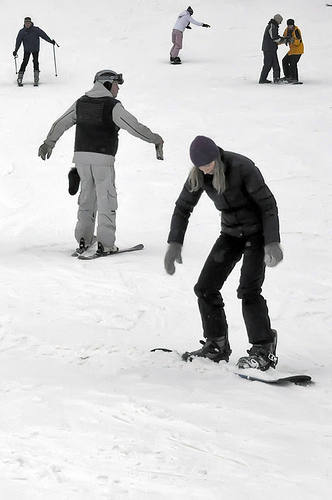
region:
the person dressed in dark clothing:
[154, 133, 310, 382]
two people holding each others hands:
[259, 13, 302, 84]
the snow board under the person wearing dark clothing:
[148, 345, 313, 382]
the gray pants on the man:
[69, 159, 119, 254]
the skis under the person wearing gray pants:
[71, 230, 144, 259]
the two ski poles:
[13, 40, 58, 76]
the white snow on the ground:
[1, 0, 329, 496]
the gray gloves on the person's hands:
[164, 242, 283, 273]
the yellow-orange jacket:
[282, 25, 302, 51]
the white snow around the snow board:
[139, 338, 317, 387]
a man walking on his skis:
[45, 59, 175, 262]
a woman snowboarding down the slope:
[149, 129, 331, 417]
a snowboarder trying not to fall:
[161, 2, 244, 79]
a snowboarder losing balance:
[162, 1, 228, 73]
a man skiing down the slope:
[4, 13, 67, 95]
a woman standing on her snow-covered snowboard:
[140, 337, 316, 411]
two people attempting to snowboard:
[255, 12, 330, 95]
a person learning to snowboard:
[282, 10, 319, 89]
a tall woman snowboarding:
[158, 130, 318, 397]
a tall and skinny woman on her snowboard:
[148, 128, 329, 386]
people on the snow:
[5, 8, 327, 441]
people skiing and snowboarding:
[11, 8, 329, 440]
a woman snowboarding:
[139, 132, 320, 431]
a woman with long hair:
[156, 120, 331, 396]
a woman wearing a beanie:
[138, 105, 313, 272]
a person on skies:
[7, 55, 172, 261]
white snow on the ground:
[141, 74, 316, 158]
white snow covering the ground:
[164, 62, 331, 159]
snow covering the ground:
[16, 330, 210, 497]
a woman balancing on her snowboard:
[140, 122, 331, 404]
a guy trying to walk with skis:
[43, 58, 161, 276]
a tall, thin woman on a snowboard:
[153, 120, 329, 421]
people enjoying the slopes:
[5, 4, 328, 397]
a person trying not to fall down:
[161, 5, 226, 75]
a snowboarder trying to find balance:
[148, 2, 231, 72]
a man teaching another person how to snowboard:
[251, 7, 329, 93]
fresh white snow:
[3, 385, 329, 492]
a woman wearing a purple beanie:
[179, 131, 225, 200]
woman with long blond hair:
[174, 125, 275, 200]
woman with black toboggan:
[154, 131, 279, 212]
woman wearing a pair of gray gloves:
[158, 114, 291, 272]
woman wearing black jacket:
[140, 120, 296, 280]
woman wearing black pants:
[172, 100, 282, 359]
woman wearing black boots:
[186, 125, 294, 372]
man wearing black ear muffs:
[52, 64, 158, 266]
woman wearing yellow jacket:
[279, 8, 322, 95]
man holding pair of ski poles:
[0, 18, 74, 89]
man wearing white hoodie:
[145, 5, 220, 70]